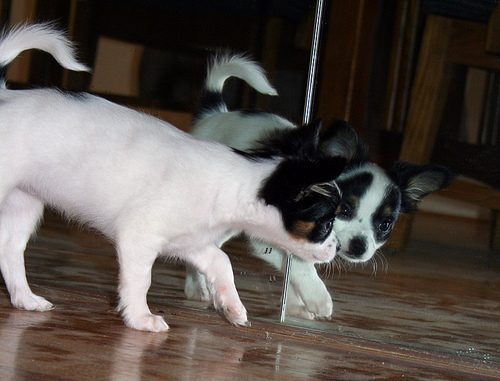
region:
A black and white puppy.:
[1, 18, 344, 331]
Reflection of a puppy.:
[251, 110, 459, 323]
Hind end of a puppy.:
[188, 50, 293, 150]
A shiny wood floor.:
[0, 285, 496, 380]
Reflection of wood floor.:
[216, 227, 496, 357]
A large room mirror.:
[0, 0, 497, 365]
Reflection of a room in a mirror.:
[0, 0, 498, 368]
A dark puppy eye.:
[323, 218, 334, 233]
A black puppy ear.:
[395, 160, 458, 208]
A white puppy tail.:
[0, 13, 92, 88]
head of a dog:
[255, 148, 359, 272]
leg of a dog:
[182, 198, 262, 320]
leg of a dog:
[97, 249, 189, 343]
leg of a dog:
[2, 192, 73, 333]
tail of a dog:
[0, 16, 117, 90]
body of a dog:
[20, 53, 248, 260]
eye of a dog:
[319, 199, 347, 231]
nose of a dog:
[347, 228, 378, 259]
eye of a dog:
[375, 202, 413, 232]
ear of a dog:
[396, 152, 456, 214]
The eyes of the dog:
[336, 205, 389, 232]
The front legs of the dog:
[117, 240, 251, 327]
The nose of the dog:
[348, 234, 365, 256]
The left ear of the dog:
[408, 166, 449, 204]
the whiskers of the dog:
[371, 248, 386, 274]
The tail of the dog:
[199, 56, 277, 116]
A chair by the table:
[383, 4, 499, 251]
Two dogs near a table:
[1, 21, 459, 333]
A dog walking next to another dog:
[0, 21, 342, 334]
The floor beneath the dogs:
[0, 212, 497, 378]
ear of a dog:
[286, 135, 344, 187]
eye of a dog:
[305, 202, 350, 240]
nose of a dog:
[325, 235, 347, 270]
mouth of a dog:
[279, 253, 330, 270]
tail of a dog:
[189, 56, 276, 110]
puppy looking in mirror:
[3, 8, 353, 358]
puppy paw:
[114, 299, 172, 339]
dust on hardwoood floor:
[26, 333, 109, 372]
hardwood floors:
[1, 276, 495, 376]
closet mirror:
[21, 46, 498, 362]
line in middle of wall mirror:
[265, 45, 329, 342]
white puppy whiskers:
[359, 243, 395, 280]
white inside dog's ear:
[408, 183, 429, 205]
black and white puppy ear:
[393, 155, 464, 232]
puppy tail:
[196, 48, 281, 119]